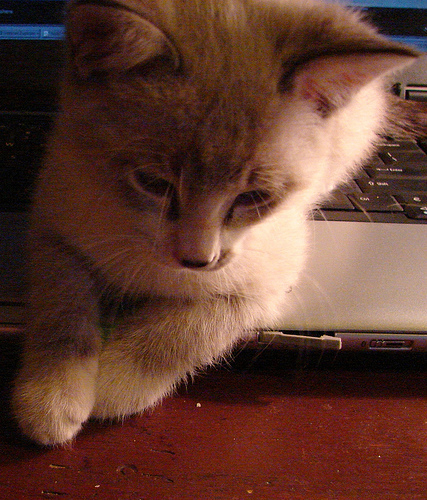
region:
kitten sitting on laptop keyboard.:
[10, 16, 408, 425]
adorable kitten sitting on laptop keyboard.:
[23, 13, 402, 384]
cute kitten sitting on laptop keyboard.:
[31, 16, 406, 383]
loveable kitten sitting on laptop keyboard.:
[35, 15, 404, 416]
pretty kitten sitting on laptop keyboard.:
[31, 13, 397, 405]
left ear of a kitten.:
[280, 24, 417, 127]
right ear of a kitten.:
[34, 2, 210, 110]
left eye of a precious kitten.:
[231, 175, 282, 237]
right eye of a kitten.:
[122, 156, 183, 220]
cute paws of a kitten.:
[12, 308, 173, 456]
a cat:
[27, 4, 402, 491]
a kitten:
[7, 6, 416, 485]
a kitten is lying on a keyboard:
[17, 10, 401, 483]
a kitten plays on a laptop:
[10, 2, 422, 492]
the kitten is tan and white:
[19, 0, 394, 470]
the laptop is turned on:
[15, 0, 423, 495]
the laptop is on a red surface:
[13, 9, 424, 487]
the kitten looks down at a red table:
[19, 8, 413, 452]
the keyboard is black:
[0, 33, 423, 283]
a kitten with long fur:
[5, 7, 422, 487]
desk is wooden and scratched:
[14, 386, 336, 497]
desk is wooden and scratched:
[21, 412, 221, 496]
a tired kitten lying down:
[2, 0, 412, 446]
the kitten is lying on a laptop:
[9, 0, 416, 484]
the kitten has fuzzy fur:
[10, 2, 420, 449]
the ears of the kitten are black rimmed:
[63, 2, 424, 126]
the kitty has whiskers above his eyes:
[16, 138, 348, 254]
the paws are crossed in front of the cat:
[3, 263, 241, 449]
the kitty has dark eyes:
[117, 159, 276, 225]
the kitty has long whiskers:
[2, 230, 335, 358]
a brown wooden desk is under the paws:
[2, 368, 421, 490]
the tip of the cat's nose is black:
[172, 253, 219, 274]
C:
[33, 8, 393, 358]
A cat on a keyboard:
[34, 11, 425, 264]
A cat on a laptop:
[17, 17, 422, 295]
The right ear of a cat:
[44, 4, 182, 98]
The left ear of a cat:
[294, 11, 420, 159]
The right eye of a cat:
[121, 128, 178, 219]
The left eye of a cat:
[228, 165, 297, 237]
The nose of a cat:
[147, 224, 218, 278]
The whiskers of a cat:
[76, 226, 314, 325]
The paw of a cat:
[18, 349, 96, 456]